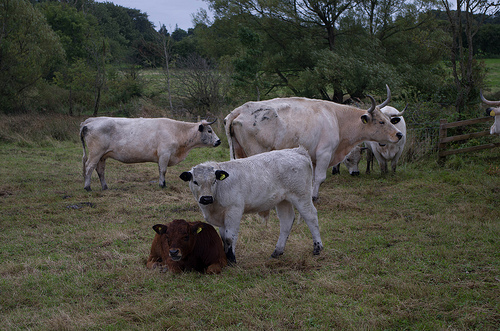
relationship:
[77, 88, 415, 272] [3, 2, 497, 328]
cows in pasture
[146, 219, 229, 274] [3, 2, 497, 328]
cow in pasture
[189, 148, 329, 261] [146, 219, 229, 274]
cow behind cow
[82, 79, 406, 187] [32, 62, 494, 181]
cows in back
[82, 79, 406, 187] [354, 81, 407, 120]
cows with horns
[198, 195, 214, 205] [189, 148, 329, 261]
nose of cow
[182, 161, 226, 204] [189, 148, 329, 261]
head of cow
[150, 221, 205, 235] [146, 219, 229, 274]
ears of cow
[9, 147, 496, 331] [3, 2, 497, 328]
grass in field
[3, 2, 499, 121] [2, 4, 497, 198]
trees in background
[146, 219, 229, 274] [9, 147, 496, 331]
cow on ground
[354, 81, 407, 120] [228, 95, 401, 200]
horns of cow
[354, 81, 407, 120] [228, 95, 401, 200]
horns of animal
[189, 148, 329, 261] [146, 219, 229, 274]
animal by animal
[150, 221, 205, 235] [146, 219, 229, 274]
ears of animal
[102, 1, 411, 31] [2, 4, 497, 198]
sky in background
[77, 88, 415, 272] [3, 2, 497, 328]
cows in field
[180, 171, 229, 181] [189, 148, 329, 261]
ears of cow